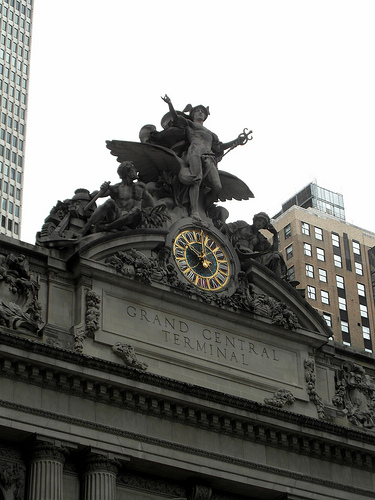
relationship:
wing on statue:
[203, 169, 255, 203] [40, 85, 302, 292]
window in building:
[302, 241, 312, 258] [258, 181, 374, 355]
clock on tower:
[170, 227, 234, 289] [41, 97, 332, 333]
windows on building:
[301, 222, 374, 353] [258, 181, 374, 355]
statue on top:
[103, 91, 255, 229] [16, 78, 347, 328]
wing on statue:
[102, 139, 182, 195] [103, 91, 255, 229]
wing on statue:
[205, 169, 255, 202] [103, 91, 255, 229]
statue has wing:
[103, 91, 255, 229] [103, 138, 186, 191]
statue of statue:
[103, 91, 255, 229] [103, 91, 255, 229]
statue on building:
[103, 91, 255, 229] [0, 92, 374, 499]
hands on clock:
[198, 224, 210, 258] [170, 221, 234, 297]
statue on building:
[101, 91, 259, 233] [2, 80, 373, 495]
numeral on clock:
[212, 246, 228, 261] [168, 220, 241, 298]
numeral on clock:
[217, 258, 230, 275] [168, 220, 241, 298]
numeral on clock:
[208, 276, 221, 291] [168, 220, 241, 298]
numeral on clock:
[182, 266, 198, 283] [168, 220, 241, 298]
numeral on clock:
[173, 244, 187, 257] [168, 220, 241, 298]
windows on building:
[277, 182, 372, 351] [266, 204, 362, 351]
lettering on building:
[107, 284, 308, 385] [7, 180, 354, 495]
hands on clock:
[182, 227, 213, 268] [173, 206, 246, 312]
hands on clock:
[184, 228, 215, 267] [151, 193, 234, 277]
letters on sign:
[118, 306, 293, 376] [89, 266, 316, 402]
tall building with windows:
[262, 182, 368, 368] [333, 235, 364, 271]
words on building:
[118, 303, 285, 375] [43, 55, 374, 498]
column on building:
[84, 463, 118, 497] [2, 80, 373, 495]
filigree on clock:
[176, 231, 231, 292] [170, 227, 234, 289]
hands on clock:
[180, 233, 209, 271] [164, 222, 234, 292]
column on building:
[84, 456, 118, 499] [2, 80, 373, 495]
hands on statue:
[210, 123, 251, 166] [123, 73, 257, 220]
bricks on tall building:
[292, 237, 321, 312] [270, 175, 346, 223]